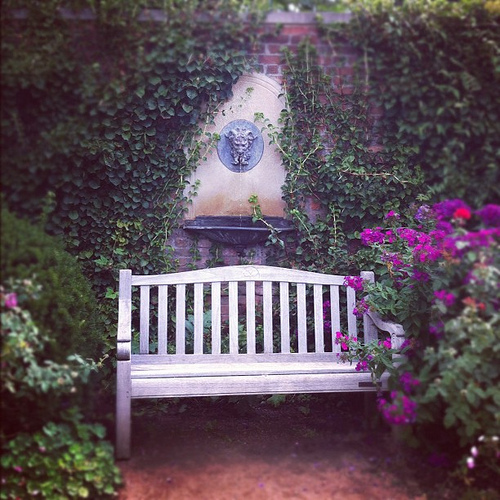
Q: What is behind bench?
A: Painting.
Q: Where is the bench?
A: Garden.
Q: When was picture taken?
A: Daytime.